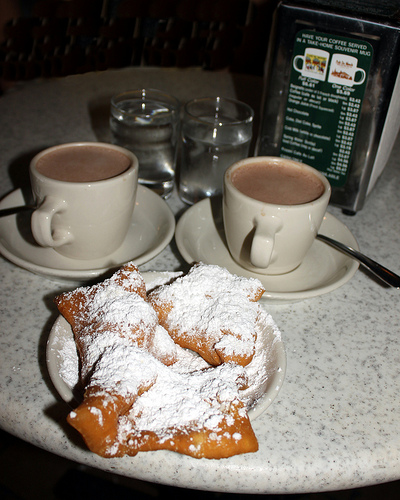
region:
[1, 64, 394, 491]
round white speckled table in a restaurant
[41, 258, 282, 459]
three pieces of pastry with white powdered sugar on them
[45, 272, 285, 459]
white plate holding pastry with powdered sugar on it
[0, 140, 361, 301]
two coffee cups and saucers with a spoon on each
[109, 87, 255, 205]
two clear glasses with water in them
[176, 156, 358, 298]
white cut and saucer with hot chocolate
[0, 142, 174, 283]
white cup and saucer with hot chocolate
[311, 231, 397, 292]
stainless steel spoon on a white saucer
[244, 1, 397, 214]
hot beverate machine on a white speckled table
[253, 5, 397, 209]
dark green sign with two white cups on it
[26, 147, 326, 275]
two cups of chocolate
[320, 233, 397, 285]
part of a silver spoon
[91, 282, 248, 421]
sugar on the cakes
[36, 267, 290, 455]
three cakes on a white dish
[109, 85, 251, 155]
two glass of water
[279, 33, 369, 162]
illegible menu of the restaurant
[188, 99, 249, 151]
a cold water glass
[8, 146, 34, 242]
the shadow of one chocolate cup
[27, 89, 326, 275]
two glass of cold water with two cups of chocolate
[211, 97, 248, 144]
the light reflected on the glass of water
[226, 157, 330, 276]
a cup of coffee with milk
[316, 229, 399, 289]
handle of a utensil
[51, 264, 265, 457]
pasties with powdered sugar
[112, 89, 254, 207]
two glasses of a water on a table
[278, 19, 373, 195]
a green menu on a metal napkin dispenser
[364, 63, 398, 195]
a white napkin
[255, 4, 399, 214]
a metal napkin dispenser on a table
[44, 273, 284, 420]
a white plate with pastries and powdered sugar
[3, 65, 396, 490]
gray and white surface of a round table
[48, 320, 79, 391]
powdered sugar on a white plate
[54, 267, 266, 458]
Frosted sugar on the food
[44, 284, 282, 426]
A small plate on the table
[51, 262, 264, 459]
A fried food on the plate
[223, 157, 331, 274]
A cup full of a beverage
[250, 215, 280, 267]
A handle on the cup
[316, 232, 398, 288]
Silverware on the plate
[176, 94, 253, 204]
A cup full of water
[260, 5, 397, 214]
A menu by the cups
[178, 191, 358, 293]
A plate beneath the small cup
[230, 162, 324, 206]
A brown beverage in the cup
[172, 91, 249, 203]
A clear glass of water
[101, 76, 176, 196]
A glass of water sits on the table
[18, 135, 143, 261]
A cup of capachino sits on a plate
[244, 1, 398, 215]
A napkin dispensor sits on the table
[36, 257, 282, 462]
A plate of powered treats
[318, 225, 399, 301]
A spoon lays next to a cup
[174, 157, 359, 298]
A plate with a cup on it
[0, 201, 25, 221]
A spoon lays on a plate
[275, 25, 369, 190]
A menu on the side of a napkin dispenser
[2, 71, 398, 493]
A white and grey table